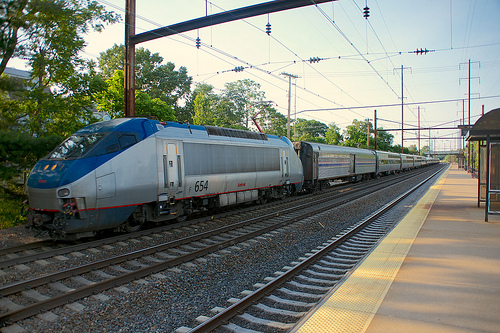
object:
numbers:
[194, 180, 209, 193]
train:
[20, 110, 442, 241]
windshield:
[48, 133, 105, 158]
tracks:
[189, 166, 451, 333]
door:
[155, 138, 186, 202]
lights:
[50, 164, 57, 171]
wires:
[298, 0, 436, 130]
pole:
[287, 76, 292, 141]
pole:
[400, 63, 404, 154]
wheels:
[124, 220, 142, 233]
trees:
[0, 0, 65, 77]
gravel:
[0, 163, 451, 332]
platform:
[294, 155, 500, 332]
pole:
[366, 118, 370, 150]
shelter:
[466, 108, 499, 222]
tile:
[294, 159, 452, 331]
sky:
[1, 0, 500, 154]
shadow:
[314, 190, 497, 332]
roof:
[0, 66, 41, 80]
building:
[0, 65, 50, 151]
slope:
[24, 116, 131, 188]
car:
[27, 114, 306, 242]